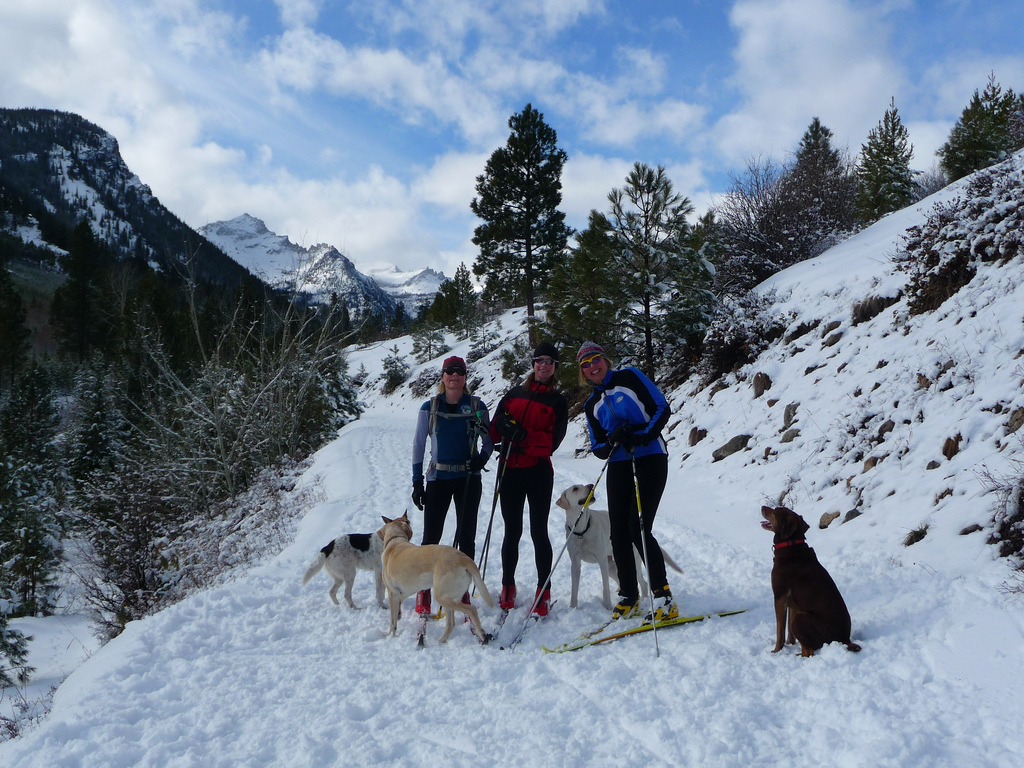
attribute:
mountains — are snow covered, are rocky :
[191, 212, 470, 327]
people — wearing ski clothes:
[410, 340, 676, 626]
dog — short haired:
[378, 514, 489, 647]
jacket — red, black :
[493, 383, 567, 472]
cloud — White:
[483, 45, 708, 143]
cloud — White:
[707, 0, 1012, 198]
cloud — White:
[0, 4, 425, 242]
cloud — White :
[242, 5, 528, 136]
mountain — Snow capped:
[187, 204, 403, 325]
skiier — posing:
[577, 335, 682, 630]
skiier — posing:
[481, 339, 568, 625]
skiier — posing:
[407, 352, 496, 548]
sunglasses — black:
[442, 361, 471, 372]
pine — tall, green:
[471, 102, 574, 338]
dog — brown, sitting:
[754, 497, 860, 653]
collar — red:
[776, 532, 808, 553]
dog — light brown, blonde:
[373, 507, 506, 653]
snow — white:
[209, 219, 328, 290]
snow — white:
[18, 128, 149, 264]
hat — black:
[527, 338, 567, 361]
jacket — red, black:
[490, 381, 570, 480]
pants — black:
[495, 455, 557, 586]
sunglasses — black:
[435, 367, 471, 387]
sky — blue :
[6, 0, 1022, 304]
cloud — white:
[707, 0, 982, 172]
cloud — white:
[381, 5, 707, 152]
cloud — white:
[414, 131, 744, 230]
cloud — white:
[75, 0, 303, 138]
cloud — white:
[6, 0, 436, 266]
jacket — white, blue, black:
[588, 355, 671, 467]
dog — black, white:
[302, 509, 411, 612]